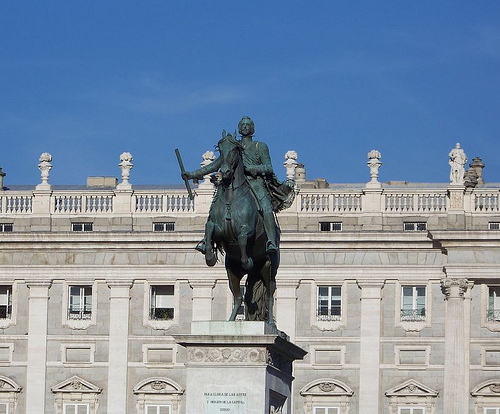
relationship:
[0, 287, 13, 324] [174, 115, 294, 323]
window facing statue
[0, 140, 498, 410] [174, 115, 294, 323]
building behind statue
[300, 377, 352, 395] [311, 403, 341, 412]
stone on window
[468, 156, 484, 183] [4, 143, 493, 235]
chimney on roof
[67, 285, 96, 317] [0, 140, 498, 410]
window on building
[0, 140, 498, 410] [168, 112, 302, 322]
building behind statue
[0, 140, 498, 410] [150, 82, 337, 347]
building behind statue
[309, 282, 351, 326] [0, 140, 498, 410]
window on building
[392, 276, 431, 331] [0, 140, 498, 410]
window on building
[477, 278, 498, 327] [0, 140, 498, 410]
window on building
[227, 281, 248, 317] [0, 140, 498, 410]
window on building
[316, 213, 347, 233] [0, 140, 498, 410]
window on building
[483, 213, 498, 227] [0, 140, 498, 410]
window on building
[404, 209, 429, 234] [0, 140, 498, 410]
window on building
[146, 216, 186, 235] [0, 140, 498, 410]
window on building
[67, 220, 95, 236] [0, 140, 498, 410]
window on building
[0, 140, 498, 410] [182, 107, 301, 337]
building facing statue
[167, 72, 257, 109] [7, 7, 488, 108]
cloud in sky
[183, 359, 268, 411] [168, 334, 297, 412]
writing on column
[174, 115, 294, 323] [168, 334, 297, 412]
statue on column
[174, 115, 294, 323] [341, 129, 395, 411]
statue on column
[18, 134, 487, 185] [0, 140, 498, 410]
posts on building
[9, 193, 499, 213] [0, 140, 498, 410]
barriers on building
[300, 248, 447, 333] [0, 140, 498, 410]
windows on building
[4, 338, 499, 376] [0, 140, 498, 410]
design on building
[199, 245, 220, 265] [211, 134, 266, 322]
feet of horse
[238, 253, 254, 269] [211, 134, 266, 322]
feet of horse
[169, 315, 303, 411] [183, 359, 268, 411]
pedestal with writing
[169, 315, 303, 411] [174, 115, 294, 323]
pedestal under statue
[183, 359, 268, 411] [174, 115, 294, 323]
writing under statue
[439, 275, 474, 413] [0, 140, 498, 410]
stone column in front of building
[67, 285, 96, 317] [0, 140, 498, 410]
window on front of building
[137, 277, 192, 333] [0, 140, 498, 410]
window on building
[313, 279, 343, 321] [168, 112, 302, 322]
window facing statue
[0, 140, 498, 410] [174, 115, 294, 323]
building by statue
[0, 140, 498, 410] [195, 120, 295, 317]
building facing statue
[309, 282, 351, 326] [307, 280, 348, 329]
window with frame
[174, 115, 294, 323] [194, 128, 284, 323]
statue on horse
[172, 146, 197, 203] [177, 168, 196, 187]
sword in hand